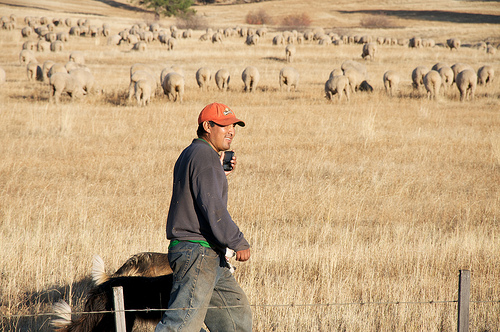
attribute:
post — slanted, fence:
[110, 284, 126, 330]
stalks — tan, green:
[296, 231, 383, 282]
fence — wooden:
[19, 266, 497, 322]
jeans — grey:
[154, 237, 255, 329]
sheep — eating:
[4, 11, 497, 106]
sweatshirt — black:
[167, 140, 247, 258]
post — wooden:
[457, 267, 472, 327]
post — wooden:
[111, 285, 130, 330]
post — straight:
[455, 263, 475, 330]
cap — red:
[193, 96, 248, 130]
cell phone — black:
[224, 151, 231, 168]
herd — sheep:
[7, 15, 496, 100]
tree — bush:
[361, 15, 406, 27]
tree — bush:
[246, 10, 312, 30]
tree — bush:
[174, 12, 207, 28]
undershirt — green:
[165, 236, 215, 253]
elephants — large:
[323, 74, 349, 104]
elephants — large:
[276, 64, 303, 89]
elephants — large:
[239, 65, 260, 91]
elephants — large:
[213, 65, 229, 90]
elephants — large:
[193, 65, 213, 88]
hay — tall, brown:
[4, 4, 484, 324]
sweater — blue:
[164, 137, 251, 251]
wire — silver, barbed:
[14, 293, 498, 331]